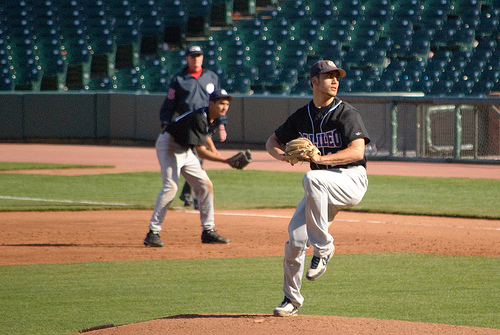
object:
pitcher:
[264, 56, 369, 315]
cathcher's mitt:
[284, 135, 322, 161]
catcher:
[141, 87, 252, 248]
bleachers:
[91, 76, 117, 91]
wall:
[0, 90, 500, 164]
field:
[0, 139, 500, 334]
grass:
[0, 162, 499, 220]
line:
[1, 193, 500, 232]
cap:
[308, 59, 347, 79]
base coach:
[157, 45, 230, 213]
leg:
[299, 169, 365, 283]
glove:
[226, 148, 254, 171]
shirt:
[270, 97, 371, 170]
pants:
[281, 162, 368, 307]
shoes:
[304, 246, 335, 282]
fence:
[385, 98, 500, 165]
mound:
[74, 312, 500, 335]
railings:
[387, 100, 414, 159]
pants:
[146, 132, 219, 238]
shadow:
[79, 312, 277, 334]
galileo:
[300, 129, 344, 149]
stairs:
[24, 68, 45, 92]